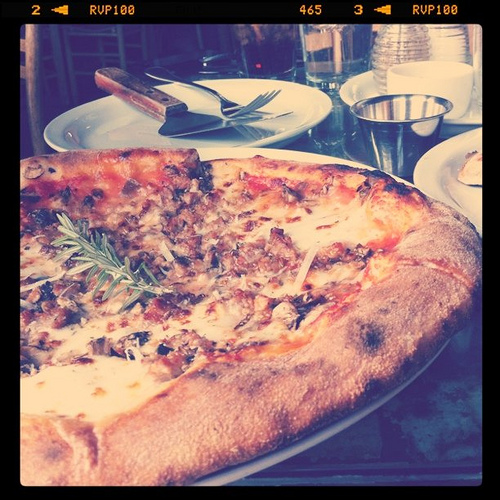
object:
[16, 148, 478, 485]
pizza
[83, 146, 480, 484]
plate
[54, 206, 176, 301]
green leaf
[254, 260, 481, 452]
crust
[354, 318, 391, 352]
burn mark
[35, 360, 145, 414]
cheese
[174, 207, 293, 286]
sausage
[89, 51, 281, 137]
utensils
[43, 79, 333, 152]
white plate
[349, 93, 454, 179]
bowl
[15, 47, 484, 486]
table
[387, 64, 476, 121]
white bowl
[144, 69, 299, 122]
fork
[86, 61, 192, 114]
handle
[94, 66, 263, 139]
spatula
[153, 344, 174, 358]
black olives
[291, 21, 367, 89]
glass cup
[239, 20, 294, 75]
condiments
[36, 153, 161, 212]
sauce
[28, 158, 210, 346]
toppings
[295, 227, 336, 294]
onion